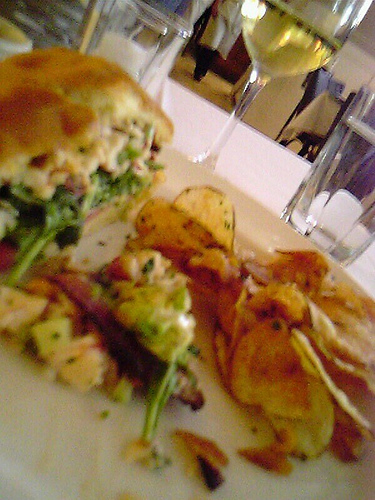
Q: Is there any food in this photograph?
A: Yes, there is food.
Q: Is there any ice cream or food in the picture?
A: Yes, there is food.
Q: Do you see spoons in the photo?
A: No, there are no spoons.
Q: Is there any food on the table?
A: Yes, there is food on the table.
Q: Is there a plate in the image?
A: Yes, there is a plate.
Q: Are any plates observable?
A: Yes, there is a plate.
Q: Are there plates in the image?
A: Yes, there is a plate.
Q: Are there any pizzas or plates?
A: Yes, there is a plate.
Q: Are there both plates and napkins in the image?
A: No, there is a plate but no napkins.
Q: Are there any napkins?
A: No, there are no napkins.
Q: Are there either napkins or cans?
A: No, there are no napkins or cans.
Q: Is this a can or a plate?
A: This is a plate.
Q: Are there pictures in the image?
A: No, there are no pictures.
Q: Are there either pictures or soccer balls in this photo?
A: No, there are no pictures or soccer balls.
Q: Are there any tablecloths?
A: Yes, there is a tablecloth.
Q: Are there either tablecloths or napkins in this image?
A: Yes, there is a tablecloth.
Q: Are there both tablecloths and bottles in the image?
A: No, there is a tablecloth but no bottles.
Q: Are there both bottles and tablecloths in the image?
A: No, there is a tablecloth but no bottles.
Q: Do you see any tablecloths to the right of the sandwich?
A: Yes, there is a tablecloth to the right of the sandwich.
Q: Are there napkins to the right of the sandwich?
A: No, there is a tablecloth to the right of the sandwich.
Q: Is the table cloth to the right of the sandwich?
A: Yes, the table cloth is to the right of the sandwich.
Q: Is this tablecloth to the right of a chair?
A: No, the tablecloth is to the right of the sandwich.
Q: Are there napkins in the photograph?
A: No, there are no napkins.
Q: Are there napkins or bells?
A: No, there are no napkins or bells.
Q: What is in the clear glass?
A: The water is in the glass.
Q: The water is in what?
A: The water is in the glass.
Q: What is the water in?
A: The water is in the glass.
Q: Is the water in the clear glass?
A: Yes, the water is in the glass.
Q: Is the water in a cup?
A: No, the water is in the glass.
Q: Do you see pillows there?
A: No, there are no pillows.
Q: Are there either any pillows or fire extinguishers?
A: No, there are no pillows or fire extinguishers.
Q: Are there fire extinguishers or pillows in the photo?
A: No, there are no pillows or fire extinguishers.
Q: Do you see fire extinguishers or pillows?
A: No, there are no pillows or fire extinguishers.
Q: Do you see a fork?
A: No, there are no forks.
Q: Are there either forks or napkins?
A: No, there are no forks or napkins.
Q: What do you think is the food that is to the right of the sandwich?
A: The food is potato chips.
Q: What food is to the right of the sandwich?
A: The food is potato chips.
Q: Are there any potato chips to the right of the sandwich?
A: Yes, there are potato chips to the right of the sandwich.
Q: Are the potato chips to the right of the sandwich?
A: Yes, the potato chips are to the right of the sandwich.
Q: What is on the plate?
A: The potato chips are on the plate.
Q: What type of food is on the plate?
A: The food is potato chips.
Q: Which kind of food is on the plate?
A: The food is potato chips.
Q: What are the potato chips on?
A: The potato chips are on the plate.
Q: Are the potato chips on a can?
A: No, the potato chips are on the plate.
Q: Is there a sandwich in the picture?
A: Yes, there is a sandwich.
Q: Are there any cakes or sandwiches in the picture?
A: Yes, there is a sandwich.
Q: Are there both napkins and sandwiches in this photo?
A: No, there is a sandwich but no napkins.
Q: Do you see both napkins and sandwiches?
A: No, there is a sandwich but no napkins.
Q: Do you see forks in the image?
A: No, there are no forks.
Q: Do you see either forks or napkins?
A: No, there are no forks or napkins.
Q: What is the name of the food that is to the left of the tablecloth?
A: The food is a sandwich.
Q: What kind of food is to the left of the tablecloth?
A: The food is a sandwich.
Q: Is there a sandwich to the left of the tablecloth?
A: Yes, there is a sandwich to the left of the tablecloth.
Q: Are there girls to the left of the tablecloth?
A: No, there is a sandwich to the left of the tablecloth.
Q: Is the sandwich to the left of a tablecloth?
A: Yes, the sandwich is to the left of a tablecloth.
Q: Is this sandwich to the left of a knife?
A: No, the sandwich is to the left of a tablecloth.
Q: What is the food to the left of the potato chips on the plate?
A: The food is a sandwich.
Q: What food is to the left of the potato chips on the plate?
A: The food is a sandwich.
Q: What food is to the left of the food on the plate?
A: The food is a sandwich.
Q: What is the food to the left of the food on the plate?
A: The food is a sandwich.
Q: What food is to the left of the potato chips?
A: The food is a sandwich.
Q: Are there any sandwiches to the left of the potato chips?
A: Yes, there is a sandwich to the left of the potato chips.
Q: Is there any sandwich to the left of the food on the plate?
A: Yes, there is a sandwich to the left of the potato chips.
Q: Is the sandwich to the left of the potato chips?
A: Yes, the sandwich is to the left of the potato chips.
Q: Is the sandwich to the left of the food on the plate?
A: Yes, the sandwich is to the left of the potato chips.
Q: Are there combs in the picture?
A: No, there are no combs.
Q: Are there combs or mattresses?
A: No, there are no combs or mattresses.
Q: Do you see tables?
A: Yes, there is a table.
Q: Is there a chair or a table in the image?
A: Yes, there is a table.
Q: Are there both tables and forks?
A: No, there is a table but no forks.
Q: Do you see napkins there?
A: No, there are no napkins.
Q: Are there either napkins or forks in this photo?
A: No, there are no napkins or forks.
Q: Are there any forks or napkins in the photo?
A: No, there are no napkins or forks.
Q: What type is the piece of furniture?
A: The piece of furniture is a table.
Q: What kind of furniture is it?
A: The piece of furniture is a table.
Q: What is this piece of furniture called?
A: That is a table.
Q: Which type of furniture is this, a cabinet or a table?
A: That is a table.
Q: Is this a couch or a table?
A: This is a table.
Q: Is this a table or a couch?
A: This is a table.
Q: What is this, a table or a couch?
A: This is a table.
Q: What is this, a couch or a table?
A: This is a table.